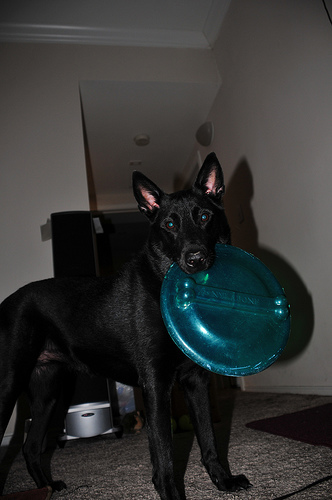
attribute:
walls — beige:
[6, 43, 330, 308]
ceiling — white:
[1, 1, 229, 50]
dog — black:
[22, 149, 253, 422]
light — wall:
[186, 114, 227, 159]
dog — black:
[1, 166, 255, 426]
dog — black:
[1, 149, 327, 498]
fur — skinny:
[63, 284, 89, 300]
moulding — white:
[30, 21, 247, 64]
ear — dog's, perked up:
[197, 149, 225, 204]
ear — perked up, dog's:
[131, 171, 166, 220]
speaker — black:
[51, 210, 110, 275]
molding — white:
[24, 21, 206, 36]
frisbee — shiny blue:
[164, 240, 283, 376]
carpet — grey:
[254, 449, 317, 497]